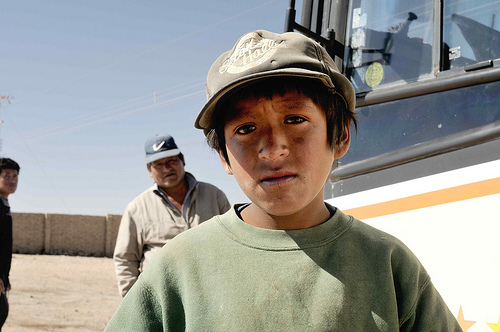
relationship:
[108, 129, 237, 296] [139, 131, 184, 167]
man wearing nike hat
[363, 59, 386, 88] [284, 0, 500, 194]
sticker on a vehicle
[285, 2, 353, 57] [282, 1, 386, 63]
mirror on side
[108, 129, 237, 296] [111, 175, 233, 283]
person wearing sweater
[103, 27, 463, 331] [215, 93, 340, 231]
person covered in dust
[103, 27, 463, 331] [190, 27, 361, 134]
boy wears a cap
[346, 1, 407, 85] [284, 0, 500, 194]
windshield on vehicle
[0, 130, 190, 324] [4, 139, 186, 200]
people look reluctant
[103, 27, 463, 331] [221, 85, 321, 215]
boy has ndicisive look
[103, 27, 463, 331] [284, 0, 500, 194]
boy beside bus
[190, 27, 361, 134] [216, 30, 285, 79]
hat has design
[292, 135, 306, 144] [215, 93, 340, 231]
mark on face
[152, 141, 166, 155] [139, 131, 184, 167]
nike logo on hat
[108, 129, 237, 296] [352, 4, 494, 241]
man standing near bus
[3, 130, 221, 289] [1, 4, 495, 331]
male looking at camera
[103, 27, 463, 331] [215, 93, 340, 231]
boy not smiling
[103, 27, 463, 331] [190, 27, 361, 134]
boy wearing cap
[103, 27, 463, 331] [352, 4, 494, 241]
boy standing near bus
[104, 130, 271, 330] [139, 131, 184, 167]
man wearing cap